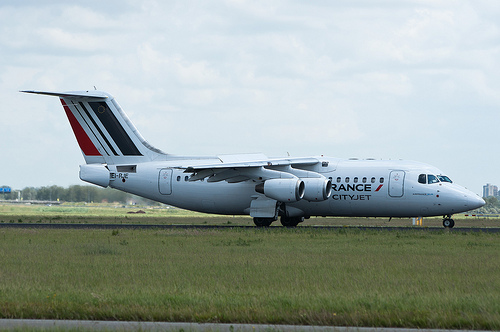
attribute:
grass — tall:
[1, 220, 498, 328]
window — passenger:
[378, 177, 383, 184]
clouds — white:
[235, 51, 353, 117]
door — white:
[158, 164, 173, 198]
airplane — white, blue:
[20, 64, 498, 260]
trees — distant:
[25, 157, 167, 235]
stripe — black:
[90, 100, 142, 153]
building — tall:
[481, 182, 498, 203]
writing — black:
[317, 170, 389, 213]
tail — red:
[17, 93, 175, 160]